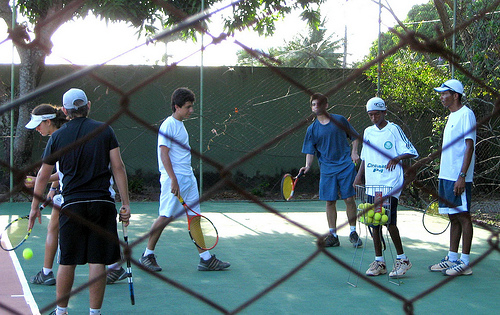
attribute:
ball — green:
[20, 245, 41, 264]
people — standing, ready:
[24, 77, 479, 315]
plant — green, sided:
[363, 21, 471, 114]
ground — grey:
[2, 199, 499, 315]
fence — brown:
[4, 1, 499, 314]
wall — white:
[0, 62, 497, 185]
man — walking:
[136, 86, 233, 286]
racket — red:
[175, 188, 222, 254]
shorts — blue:
[430, 177, 473, 216]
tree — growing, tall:
[0, 0, 350, 166]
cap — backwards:
[360, 95, 388, 113]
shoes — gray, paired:
[134, 250, 235, 275]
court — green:
[0, 200, 498, 313]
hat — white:
[62, 85, 92, 112]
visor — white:
[22, 111, 61, 132]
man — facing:
[26, 86, 132, 311]